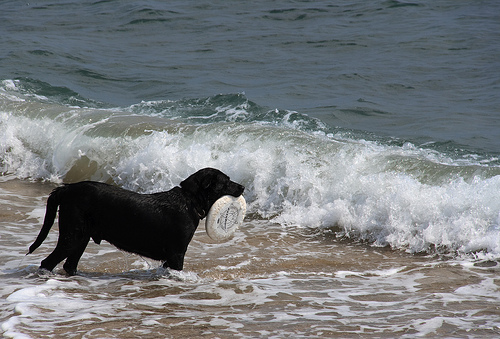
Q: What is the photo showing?
A: It is showing an ocean.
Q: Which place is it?
A: It is an ocean.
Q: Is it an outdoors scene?
A: Yes, it is outdoors.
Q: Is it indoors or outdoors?
A: It is outdoors.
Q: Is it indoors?
A: No, it is outdoors.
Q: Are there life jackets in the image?
A: No, there are no life jackets.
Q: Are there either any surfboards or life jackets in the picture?
A: No, there are no life jackets or surfboards.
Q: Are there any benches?
A: No, there are no benches.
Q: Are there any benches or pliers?
A: No, there are no benches or pliers.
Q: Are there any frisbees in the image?
A: Yes, there is a frisbee.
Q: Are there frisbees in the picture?
A: Yes, there is a frisbee.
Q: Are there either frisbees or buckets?
A: Yes, there is a frisbee.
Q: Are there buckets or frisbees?
A: Yes, there is a frisbee.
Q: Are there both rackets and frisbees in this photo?
A: No, there is a frisbee but no rackets.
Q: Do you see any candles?
A: No, there are no candles.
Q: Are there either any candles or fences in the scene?
A: No, there are no candles or fences.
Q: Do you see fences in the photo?
A: No, there are no fences.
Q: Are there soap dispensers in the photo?
A: No, there are no soap dispensers.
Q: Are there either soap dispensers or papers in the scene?
A: No, there are no soap dispensers or papers.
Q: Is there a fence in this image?
A: No, there are no fences.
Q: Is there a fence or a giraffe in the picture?
A: No, there are no fences or giraffes.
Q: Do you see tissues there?
A: No, there are no tissues.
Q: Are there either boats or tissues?
A: No, there are no tissues or boats.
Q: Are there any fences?
A: No, there are no fences.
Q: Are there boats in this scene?
A: No, there are no boats.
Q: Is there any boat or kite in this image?
A: No, there are no boats or kites.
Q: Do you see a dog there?
A: Yes, there is a dog.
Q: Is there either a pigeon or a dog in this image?
A: Yes, there is a dog.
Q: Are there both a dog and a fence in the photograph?
A: No, there is a dog but no fences.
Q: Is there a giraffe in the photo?
A: No, there are no giraffes.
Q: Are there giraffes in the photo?
A: No, there are no giraffes.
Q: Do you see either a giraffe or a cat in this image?
A: No, there are no giraffes or cats.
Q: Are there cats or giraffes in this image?
A: No, there are no giraffes or cats.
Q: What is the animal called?
A: The animal is a dog.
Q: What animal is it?
A: The animal is a dog.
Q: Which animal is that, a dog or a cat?
A: That is a dog.